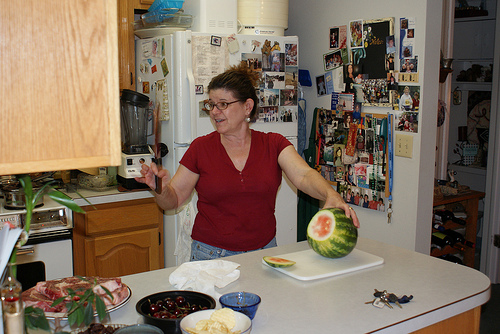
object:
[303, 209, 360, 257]
watermelon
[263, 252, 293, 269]
rind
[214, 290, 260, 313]
bowl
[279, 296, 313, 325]
countertop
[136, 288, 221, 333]
bowl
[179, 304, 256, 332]
bowl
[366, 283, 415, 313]
keys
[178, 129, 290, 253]
shirt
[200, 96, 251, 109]
glasses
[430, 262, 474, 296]
counter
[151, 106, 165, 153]
knife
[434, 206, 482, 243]
rack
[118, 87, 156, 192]
blender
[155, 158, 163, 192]
handle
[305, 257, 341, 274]
cutting board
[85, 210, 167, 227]
drawer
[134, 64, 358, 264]
woman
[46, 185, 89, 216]
leaf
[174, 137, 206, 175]
sleeve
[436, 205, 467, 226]
bottle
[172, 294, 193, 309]
cherries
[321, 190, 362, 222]
hand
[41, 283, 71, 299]
meat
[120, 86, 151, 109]
lid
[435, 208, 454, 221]
wine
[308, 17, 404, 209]
photographs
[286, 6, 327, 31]
wall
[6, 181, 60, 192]
pan